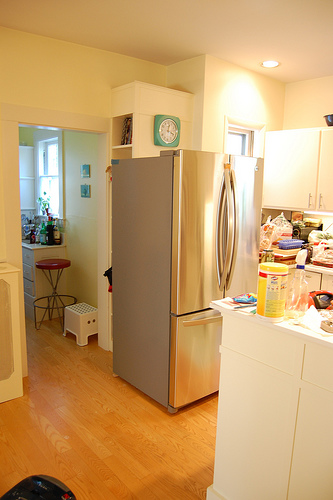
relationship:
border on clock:
[151, 114, 178, 147] [153, 114, 178, 147]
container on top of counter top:
[249, 247, 291, 327] [207, 293, 331, 497]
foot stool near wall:
[61, 301, 97, 345] [55, 124, 108, 348]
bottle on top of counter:
[283, 246, 312, 321] [208, 291, 331, 498]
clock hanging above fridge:
[154, 114, 181, 147] [111, 149, 264, 414]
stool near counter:
[33, 254, 71, 313] [21, 244, 52, 266]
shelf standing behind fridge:
[108, 112, 133, 159] [111, 149, 264, 414]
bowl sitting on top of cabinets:
[318, 105, 332, 133] [253, 102, 331, 223]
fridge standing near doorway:
[111, 149, 264, 414] [12, 111, 117, 384]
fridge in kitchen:
[111, 149, 264, 414] [17, 105, 325, 487]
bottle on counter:
[38, 221, 46, 243] [22, 235, 61, 249]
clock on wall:
[152, 113, 180, 147] [18, 46, 97, 96]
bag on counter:
[259, 215, 291, 252] [257, 255, 331, 275]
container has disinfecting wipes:
[256, 261, 288, 323] [258, 270, 291, 313]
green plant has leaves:
[37, 192, 52, 217] [37, 191, 48, 196]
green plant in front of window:
[37, 192, 52, 217] [33, 138, 63, 215]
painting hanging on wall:
[80, 164, 91, 179] [49, 123, 100, 313]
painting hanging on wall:
[80, 184, 92, 198] [49, 123, 100, 313]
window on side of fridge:
[222, 122, 256, 152] [111, 149, 264, 414]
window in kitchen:
[222, 122, 256, 152] [15, 14, 317, 494]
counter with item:
[258, 255, 332, 278] [278, 238, 306, 250]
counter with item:
[258, 255, 332, 278] [272, 246, 298, 254]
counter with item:
[258, 255, 332, 278] [313, 248, 331, 264]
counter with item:
[258, 255, 332, 278] [259, 246, 276, 262]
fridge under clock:
[111, 149, 264, 414] [151, 111, 182, 148]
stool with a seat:
[33, 258, 78, 332] [40, 254, 70, 267]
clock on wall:
[154, 114, 181, 147] [134, 81, 193, 157]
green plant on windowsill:
[37, 192, 52, 217] [18, 208, 66, 254]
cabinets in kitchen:
[255, 126, 331, 213] [2, 30, 332, 497]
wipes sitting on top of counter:
[257, 260, 289, 322] [290, 311, 329, 345]